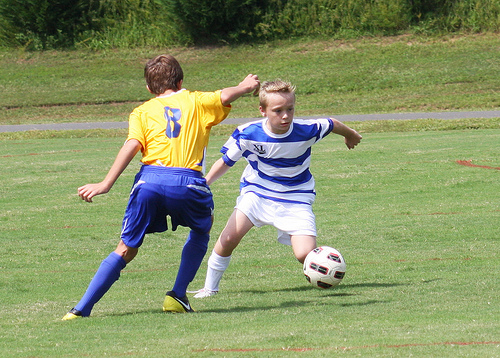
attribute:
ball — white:
[300, 243, 352, 293]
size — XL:
[250, 135, 270, 160]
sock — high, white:
[198, 250, 226, 293]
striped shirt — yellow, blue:
[220, 110, 333, 210]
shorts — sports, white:
[234, 187, 331, 248]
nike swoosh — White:
[172, 296, 193, 309]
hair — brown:
[142, 52, 185, 98]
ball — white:
[299, 246, 346, 295]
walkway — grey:
[1, 103, 498, 138]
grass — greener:
[286, 54, 469, 84]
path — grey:
[6, 106, 494, 133]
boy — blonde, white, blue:
[197, 81, 361, 291]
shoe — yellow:
[163, 288, 200, 317]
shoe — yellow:
[193, 287, 220, 302]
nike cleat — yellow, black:
[163, 282, 211, 317]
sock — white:
[205, 253, 229, 294]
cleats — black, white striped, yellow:
[154, 286, 205, 331]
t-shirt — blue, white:
[232, 117, 334, 199]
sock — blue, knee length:
[87, 254, 129, 313]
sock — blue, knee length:
[167, 224, 209, 298]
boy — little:
[62, 54, 260, 320]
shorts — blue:
[118, 165, 215, 247]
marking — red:
[449, 148, 495, 183]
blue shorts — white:
[127, 171, 212, 226]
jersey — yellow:
[125, 94, 216, 183]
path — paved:
[0, 108, 496, 137]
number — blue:
[159, 99, 180, 140]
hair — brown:
[140, 52, 181, 93]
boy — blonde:
[189, 77, 359, 301]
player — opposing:
[195, 73, 362, 308]